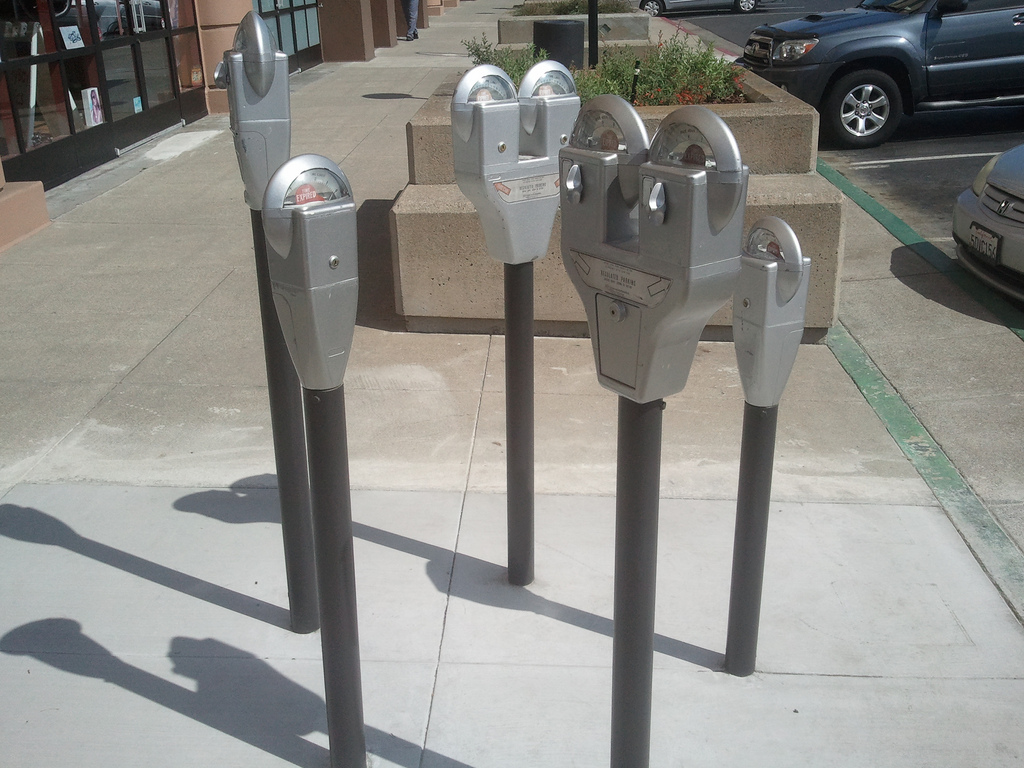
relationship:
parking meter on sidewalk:
[704, 197, 815, 682] [453, 303, 979, 755]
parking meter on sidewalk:
[227, 134, 409, 554] [13, 281, 647, 765]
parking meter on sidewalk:
[183, 1, 339, 224] [24, 175, 621, 750]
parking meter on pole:
[544, 85, 776, 470] [600, 392, 661, 725]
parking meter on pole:
[706, 193, 841, 410] [712, 393, 775, 681]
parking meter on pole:
[222, 8, 291, 211] [247, 197, 319, 643]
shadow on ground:
[0, 618, 474, 765] [1, 3, 1021, 762]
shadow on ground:
[0, 502, 294, 628] [1, 3, 1021, 762]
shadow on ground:
[182, 476, 727, 669] [1, 3, 1021, 762]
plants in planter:
[457, 27, 767, 103] [381, 50, 846, 349]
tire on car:
[801, 59, 923, 163] [743, 14, 988, 159]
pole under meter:
[604, 390, 672, 760] [534, 85, 757, 401]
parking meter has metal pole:
[722, 216, 812, 677] [714, 404, 782, 681]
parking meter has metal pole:
[441, 52, 580, 549] [493, 262, 554, 582]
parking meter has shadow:
[262, 152, 368, 768] [12, 597, 324, 764]